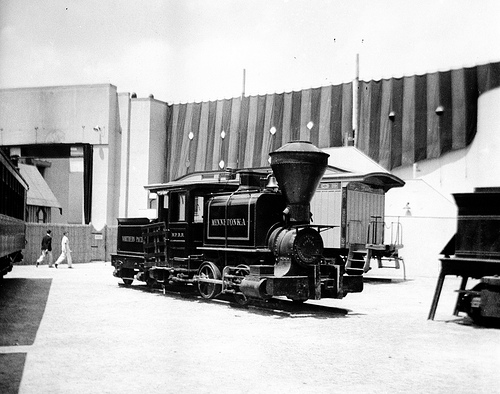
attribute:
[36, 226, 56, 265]
man — white, here, walking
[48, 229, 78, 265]
peopel — walking, together, inside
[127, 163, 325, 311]
train — black, old, displayed, car, edge, small, back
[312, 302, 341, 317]
shadows — dark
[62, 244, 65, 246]
shirt — white, dark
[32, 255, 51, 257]
pants — white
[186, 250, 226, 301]
wheel — here, steel, black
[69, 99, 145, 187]
building — here, large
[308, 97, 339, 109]
fence — wooden